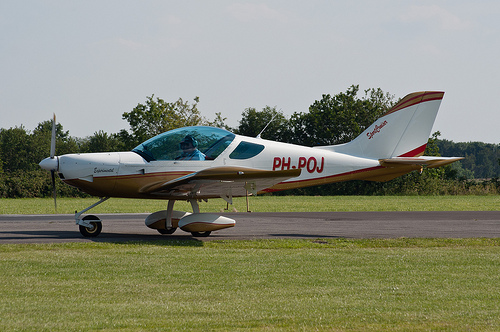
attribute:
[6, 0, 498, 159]
sky — blue 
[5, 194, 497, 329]
grass — green, strips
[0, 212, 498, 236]
paved road — gray 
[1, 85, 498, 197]
trees —  row 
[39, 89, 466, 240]
plane — white , small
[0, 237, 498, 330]
grassy area — large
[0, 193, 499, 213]
grassy area — large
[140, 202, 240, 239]
gear — landing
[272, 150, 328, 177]
letters — red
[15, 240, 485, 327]
field — behind 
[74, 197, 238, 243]
gear — landing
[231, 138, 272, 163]
window — small